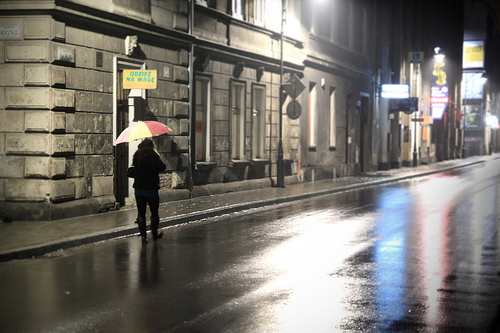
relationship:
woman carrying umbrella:
[131, 140, 166, 241] [103, 117, 175, 144]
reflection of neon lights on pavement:
[412, 169, 454, 331] [0, 151, 500, 332]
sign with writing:
[120, 67, 158, 90] [137, 70, 149, 82]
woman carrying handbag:
[131, 140, 161, 232] [125, 154, 139, 182]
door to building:
[357, 92, 372, 174] [0, 1, 374, 215]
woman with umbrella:
[131, 140, 166, 241] [108, 115, 176, 152]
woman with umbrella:
[131, 140, 166, 241] [105, 114, 174, 144]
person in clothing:
[133, 140, 167, 242] [132, 145, 165, 224]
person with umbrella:
[123, 141, 179, 240] [95, 110, 189, 144]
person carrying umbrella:
[133, 140, 167, 242] [107, 105, 182, 142]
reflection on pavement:
[402, 169, 472, 331] [0, 151, 500, 332]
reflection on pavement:
[368, 178, 412, 331] [0, 151, 500, 332]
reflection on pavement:
[209, 202, 381, 332] [0, 151, 500, 332]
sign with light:
[376, 78, 414, 99] [373, 79, 426, 109]